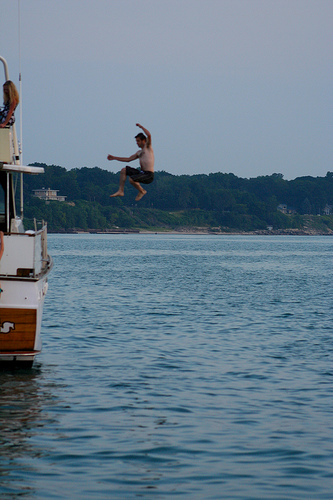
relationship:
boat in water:
[1, 58, 56, 366] [0, 228, 329, 500]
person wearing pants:
[106, 126, 159, 201] [124, 163, 156, 190]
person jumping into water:
[106, 126, 159, 201] [0, 228, 329, 500]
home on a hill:
[35, 184, 68, 205] [8, 157, 329, 232]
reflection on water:
[1, 366, 43, 468] [0, 228, 329, 500]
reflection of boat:
[1, 366, 43, 468] [1, 58, 56, 366]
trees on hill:
[12, 164, 330, 237] [8, 157, 329, 232]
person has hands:
[106, 126, 159, 201] [106, 117, 142, 164]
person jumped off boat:
[106, 126, 159, 201] [1, 58, 56, 366]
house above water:
[35, 184, 68, 205] [0, 228, 329, 500]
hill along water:
[8, 157, 329, 232] [0, 228, 329, 500]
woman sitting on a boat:
[5, 76, 23, 127] [1, 58, 56, 366]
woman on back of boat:
[5, 76, 23, 127] [1, 58, 56, 366]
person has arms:
[106, 126, 159, 201] [104, 121, 154, 163]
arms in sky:
[104, 121, 154, 163] [3, 2, 332, 175]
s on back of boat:
[3, 318, 19, 339] [1, 58, 56, 366]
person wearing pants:
[106, 126, 159, 201] [125, 165, 154, 185]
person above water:
[106, 126, 159, 201] [0, 228, 329, 500]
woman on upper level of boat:
[5, 76, 23, 127] [1, 58, 56, 366]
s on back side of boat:
[3, 318, 19, 339] [1, 58, 56, 366]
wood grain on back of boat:
[0, 309, 42, 353] [1, 58, 56, 366]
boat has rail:
[1, 58, 56, 366] [4, 223, 53, 272]